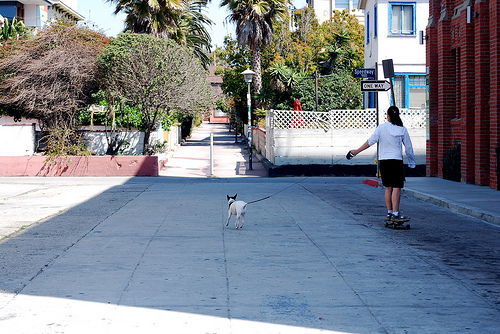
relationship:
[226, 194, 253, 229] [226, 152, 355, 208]
dog on leash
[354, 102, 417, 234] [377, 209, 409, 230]
woman on skateboard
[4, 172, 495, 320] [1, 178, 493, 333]
shadow on ground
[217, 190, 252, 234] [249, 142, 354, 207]
dog on leash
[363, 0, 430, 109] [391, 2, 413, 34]
building with window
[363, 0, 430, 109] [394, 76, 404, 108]
building with window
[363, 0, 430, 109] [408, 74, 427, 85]
building with window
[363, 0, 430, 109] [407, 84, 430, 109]
building with window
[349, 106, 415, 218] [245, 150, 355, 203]
girl holding leash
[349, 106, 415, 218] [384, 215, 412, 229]
girl riding skateboard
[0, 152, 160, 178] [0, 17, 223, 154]
wall in front of plants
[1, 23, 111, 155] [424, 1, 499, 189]
tree in front of building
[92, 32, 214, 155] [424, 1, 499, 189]
tree planted in front of building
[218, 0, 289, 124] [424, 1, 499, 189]
tree planted in front of building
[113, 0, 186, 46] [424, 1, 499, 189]
tree planted in front of building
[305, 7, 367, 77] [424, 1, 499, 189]
tree planted in front of building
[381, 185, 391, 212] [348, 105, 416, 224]
leg of a woman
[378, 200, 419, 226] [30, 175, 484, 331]
skate board on ground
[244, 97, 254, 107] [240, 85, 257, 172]
poster on post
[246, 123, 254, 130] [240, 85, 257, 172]
poster on post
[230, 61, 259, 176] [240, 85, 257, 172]
street lamp with post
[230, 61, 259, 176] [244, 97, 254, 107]
street lamp with poster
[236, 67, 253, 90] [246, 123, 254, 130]
lamp with poster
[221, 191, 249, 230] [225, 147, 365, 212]
dog on a leash